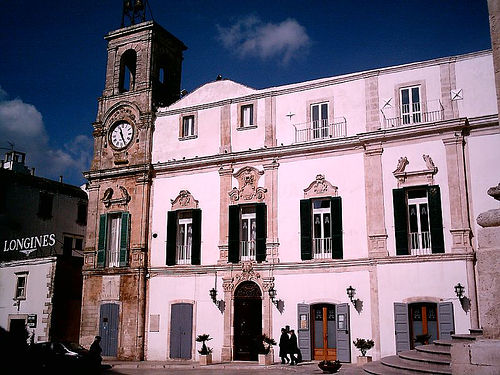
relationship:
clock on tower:
[108, 119, 134, 150] [93, 33, 140, 345]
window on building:
[96, 209, 131, 268] [43, 15, 497, 370]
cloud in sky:
[211, 9, 316, 71] [2, 1, 498, 188]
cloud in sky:
[2, 93, 91, 180] [2, 1, 498, 188]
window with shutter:
[405, 186, 432, 256] [425, 184, 445, 254]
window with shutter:
[405, 186, 432, 256] [389, 186, 409, 256]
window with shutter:
[309, 194, 331, 260] [297, 199, 315, 261]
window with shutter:
[309, 194, 331, 260] [326, 195, 344, 260]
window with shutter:
[238, 203, 255, 260] [255, 201, 265, 261]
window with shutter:
[238, 203, 255, 260] [229, 206, 239, 264]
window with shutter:
[175, 210, 191, 265] [189, 209, 202, 266]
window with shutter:
[175, 210, 191, 265] [228, 203, 240, 263]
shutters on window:
[93, 209, 108, 280] [96, 201, 135, 269]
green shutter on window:
[119, 211, 130, 267] [96, 201, 135, 269]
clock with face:
[107, 122, 138, 150] [109, 122, 131, 146]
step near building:
[362, 359, 424, 373] [43, 15, 497, 370]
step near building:
[360, 359, 451, 375] [43, 15, 497, 370]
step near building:
[398, 348, 452, 367] [43, 15, 497, 370]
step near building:
[379, 345, 451, 374] [43, 15, 497, 370]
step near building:
[449, 328, 477, 348] [43, 15, 497, 370]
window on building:
[236, 103, 255, 127] [43, 15, 497, 370]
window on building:
[182, 116, 194, 140] [43, 15, 497, 370]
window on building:
[311, 198, 333, 260] [43, 15, 497, 370]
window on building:
[309, 103, 327, 136] [43, 15, 497, 370]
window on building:
[398, 90, 426, 123] [43, 15, 497, 370]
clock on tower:
[108, 119, 134, 150] [78, 18, 189, 373]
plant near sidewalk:
[195, 336, 213, 352] [113, 360, 255, 370]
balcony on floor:
[354, 88, 472, 141] [151, 43, 498, 173]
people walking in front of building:
[278, 328, 290, 365] [131, 48, 495, 374]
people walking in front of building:
[288, 329, 300, 365] [131, 48, 495, 374]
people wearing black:
[278, 328, 290, 365] [280, 332, 286, 363]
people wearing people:
[288, 329, 300, 365] [270, 325, 310, 369]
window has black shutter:
[175, 210, 193, 265] [166, 210, 199, 262]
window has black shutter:
[238, 203, 257, 262] [226, 204, 266, 261]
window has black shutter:
[311, 198, 333, 260] [298, 195, 344, 262]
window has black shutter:
[405, 189, 432, 255] [392, 184, 447, 254]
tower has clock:
[76, 7, 149, 363] [89, 109, 157, 176]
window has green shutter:
[95, 210, 133, 265] [117, 211, 128, 264]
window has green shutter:
[95, 210, 133, 265] [98, 212, 107, 266]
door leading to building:
[308, 303, 338, 363] [43, 15, 497, 370]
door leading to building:
[411, 302, 440, 347] [43, 15, 497, 370]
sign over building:
[2, 227, 67, 266] [1, 230, 78, 350]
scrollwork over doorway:
[218, 262, 276, 293] [220, 263, 276, 373]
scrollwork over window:
[227, 166, 271, 211] [239, 207, 257, 259]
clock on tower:
[108, 119, 134, 150] [83, 15, 158, 363]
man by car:
[81, 328, 110, 373] [12, 337, 94, 373]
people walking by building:
[276, 323, 299, 366] [148, 57, 478, 367]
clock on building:
[107, 122, 138, 150] [78, 16, 186, 356]